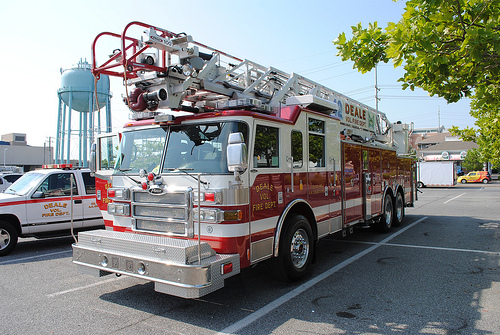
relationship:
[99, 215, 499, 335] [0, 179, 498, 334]
shadow on ground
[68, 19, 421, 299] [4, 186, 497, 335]
fire truck sitting in lot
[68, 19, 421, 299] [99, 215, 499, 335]
fire truck has a shadow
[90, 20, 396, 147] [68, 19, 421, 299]
ladder on top of fire truck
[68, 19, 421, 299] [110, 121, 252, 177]
fire truck has a windshield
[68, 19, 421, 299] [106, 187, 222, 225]
fire truck has lights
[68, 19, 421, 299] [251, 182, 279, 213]
fire truck has printed name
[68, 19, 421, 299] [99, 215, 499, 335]
fire truck casting a shadow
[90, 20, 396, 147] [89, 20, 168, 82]
ladder has rails